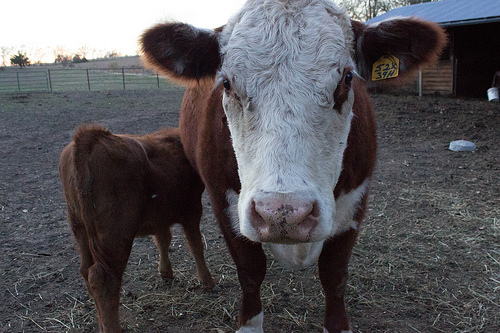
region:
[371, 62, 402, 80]
Yellow tag on a cow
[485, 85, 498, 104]
white bucket sitting on the ground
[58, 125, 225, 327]
Baby calf feeding from its mom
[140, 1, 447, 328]
Mother cow feeding its calf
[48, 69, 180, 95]
Metal holding pen fence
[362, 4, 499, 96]
Barn made out of wood and metal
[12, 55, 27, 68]
Large tree in the distance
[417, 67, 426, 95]
Wooden post on the side of the barn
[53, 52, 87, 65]
Bushes sitting in the background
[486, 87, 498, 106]
Feeding bucket for cows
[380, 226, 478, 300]
Hay covering the ground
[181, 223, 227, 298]
Right front leg of the smaller animal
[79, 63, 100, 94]
Third fence post from the left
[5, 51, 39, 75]
Tree growing in the background behind the fence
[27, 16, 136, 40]
Clear white sky in the background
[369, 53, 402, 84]
Yellow tag in the cow's left ear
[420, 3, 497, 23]
Roof of the structure in the background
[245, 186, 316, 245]
Cow's big pinkish nose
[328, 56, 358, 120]
Cow's brown left eye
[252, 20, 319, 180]
Cow's furry white face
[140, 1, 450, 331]
Adult cow in a farm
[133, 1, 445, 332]
Cow is white and brown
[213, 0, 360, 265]
Head of cow is white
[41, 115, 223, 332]
Baby cow is brown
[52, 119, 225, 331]
Baby cow is drinking milk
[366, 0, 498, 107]
Farm building has black roof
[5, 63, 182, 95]
Fence of farm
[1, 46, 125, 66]
Trees on the background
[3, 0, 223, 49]
Ski is cloudy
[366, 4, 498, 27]
Black roof of building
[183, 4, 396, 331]
this is a cow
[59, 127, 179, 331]
a calf is besides the cow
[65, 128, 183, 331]
the calf is brown in color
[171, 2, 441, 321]
the cow is staring at the camera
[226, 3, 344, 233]
the cows head is white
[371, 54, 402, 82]
a peg is placed on the cows ear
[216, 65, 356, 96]
the cows eyes are far apart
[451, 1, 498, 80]
a ranch is behind the cow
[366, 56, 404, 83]
the peg is written 5239H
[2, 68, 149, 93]
the fence is around the ranch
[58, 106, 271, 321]
Baby cow nursing from mother.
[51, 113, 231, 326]
Small brown calf.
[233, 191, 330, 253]
Spotted pink cow nose.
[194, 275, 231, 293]
Small calf hoof.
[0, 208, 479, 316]
Hay laying on the ground of a barnyard.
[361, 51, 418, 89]
Yellow tag attached to a cow's ear.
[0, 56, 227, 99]
Black metal fence.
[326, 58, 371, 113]
Brown ring encircles a cow's eye.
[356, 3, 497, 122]
A wooden building.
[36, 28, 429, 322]
A mother cow and her calf.